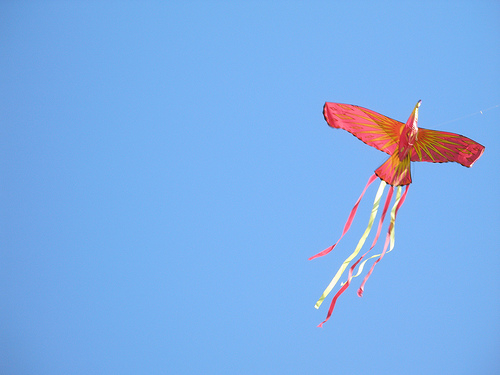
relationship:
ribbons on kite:
[303, 173, 411, 332] [321, 96, 484, 189]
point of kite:
[414, 96, 424, 108] [321, 96, 484, 189]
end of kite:
[413, 95, 423, 112] [321, 96, 484, 189]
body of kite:
[395, 103, 421, 163] [321, 96, 484, 189]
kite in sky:
[321, 96, 484, 189] [2, 1, 479, 372]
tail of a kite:
[304, 172, 413, 330] [321, 96, 484, 189]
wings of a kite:
[320, 100, 484, 169] [321, 96, 484, 189]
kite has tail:
[301, 92, 484, 338] [375, 151, 415, 190]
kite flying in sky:
[301, 92, 484, 338] [2, 1, 479, 372]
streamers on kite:
[303, 172, 413, 332] [301, 92, 484, 338]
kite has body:
[309, 95, 482, 326] [393, 115, 423, 164]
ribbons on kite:
[303, 173, 411, 332] [301, 92, 484, 338]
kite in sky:
[301, 92, 484, 338] [2, 1, 479, 372]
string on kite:
[308, 173, 378, 263] [301, 92, 484, 338]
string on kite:
[312, 181, 385, 311] [301, 92, 484, 338]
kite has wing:
[301, 92, 484, 338] [321, 97, 402, 157]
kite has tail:
[301, 92, 484, 338] [365, 152, 418, 193]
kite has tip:
[301, 92, 484, 338] [321, 99, 333, 123]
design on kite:
[451, 139, 476, 162] [301, 92, 484, 338]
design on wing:
[412, 129, 466, 159] [409, 123, 484, 174]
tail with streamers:
[372, 149, 418, 189] [303, 172, 413, 332]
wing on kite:
[413, 125, 488, 172] [309, 95, 482, 326]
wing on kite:
[320, 100, 403, 154] [309, 95, 482, 326]